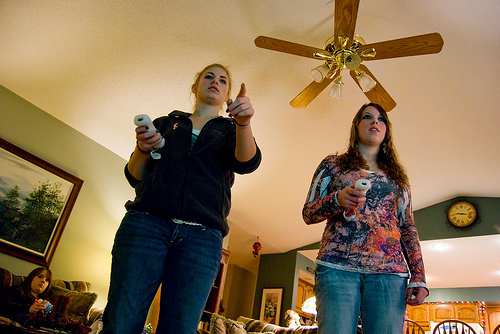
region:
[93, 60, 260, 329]
a girl playing a video game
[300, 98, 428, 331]
a girl playing a video game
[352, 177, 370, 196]
a Wii video game controller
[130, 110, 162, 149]
a Wii video game controller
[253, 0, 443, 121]
a ceiling fan with light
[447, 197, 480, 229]
a wall mounted clock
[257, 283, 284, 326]
a framed artwork print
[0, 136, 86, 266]
a framed artwork print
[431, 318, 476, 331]
a chair wood back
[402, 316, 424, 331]
a chair wood back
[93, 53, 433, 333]
two young women seen from a low angle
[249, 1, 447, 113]
a ceiling fan that appears to be off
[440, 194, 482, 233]
a round wall clock with a yellow face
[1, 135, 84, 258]
trees in an art piece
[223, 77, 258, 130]
woman pointing her index finger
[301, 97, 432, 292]
woman wearing a multicolored long-sleeved shirt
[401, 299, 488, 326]
multicolored lights draped over wooden cabinets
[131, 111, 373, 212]
white game controllers in both women's right hands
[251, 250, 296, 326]
long framed artwork on green wall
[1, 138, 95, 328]
person sitting in couch beneath artwork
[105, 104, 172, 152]
wii remote controller in girl's hand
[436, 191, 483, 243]
wooden clock with roman numerals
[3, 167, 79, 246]
painting with trees as center focus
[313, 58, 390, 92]
light fixtures in center of fan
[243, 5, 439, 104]
ceiling fan with light brown fan blades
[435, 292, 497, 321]
row of light brown cabinets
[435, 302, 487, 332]
rounded back of diningroom chairs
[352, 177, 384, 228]
woman on right holding wii remote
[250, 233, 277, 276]
red item hanging from ceiling in room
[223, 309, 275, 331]
multicolored striped sofa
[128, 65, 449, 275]
The two friends are playing wii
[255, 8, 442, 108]
Fan on the ceiling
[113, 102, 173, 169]
Woman is holding a wii remote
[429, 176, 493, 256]
Clock hanging toward the ceiling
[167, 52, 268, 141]
The woman has blonde hair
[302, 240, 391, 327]
The woman's jeans are stonewashed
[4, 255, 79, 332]
Woman sitting on the couch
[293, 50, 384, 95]
Lights attached to the fan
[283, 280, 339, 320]
Lamp is on the table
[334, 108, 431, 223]
Woman has dark hair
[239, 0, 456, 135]
Brown and white ceiling fan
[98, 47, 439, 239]
Two girls with wii remotes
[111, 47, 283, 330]
Girl pointing at TV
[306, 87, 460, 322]
Girl staring at TV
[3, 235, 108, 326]
Person watching the girls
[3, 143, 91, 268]
Forest painting on wall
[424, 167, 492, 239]
Clock on the wall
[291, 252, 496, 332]
Cupboards in the kitchen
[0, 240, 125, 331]
Striped couch with person sitting on it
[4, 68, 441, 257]
Green painted wall